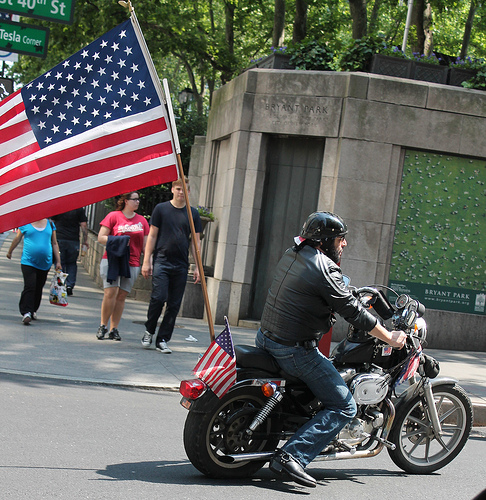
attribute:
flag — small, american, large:
[1, 19, 177, 237]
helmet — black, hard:
[301, 206, 350, 249]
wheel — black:
[390, 380, 471, 471]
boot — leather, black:
[265, 446, 322, 487]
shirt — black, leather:
[264, 244, 373, 347]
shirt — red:
[99, 211, 156, 267]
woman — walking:
[93, 191, 162, 348]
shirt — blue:
[19, 217, 58, 267]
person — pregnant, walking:
[0, 209, 69, 335]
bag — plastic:
[50, 272, 78, 306]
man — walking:
[138, 173, 209, 355]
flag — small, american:
[196, 323, 243, 401]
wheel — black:
[182, 380, 291, 485]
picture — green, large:
[392, 143, 485, 317]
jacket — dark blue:
[108, 234, 127, 284]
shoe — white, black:
[140, 334, 152, 350]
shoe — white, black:
[155, 343, 176, 353]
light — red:
[185, 379, 207, 401]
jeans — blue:
[255, 331, 358, 455]